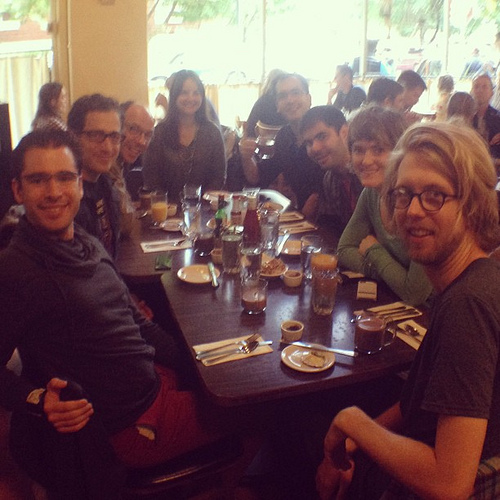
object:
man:
[320, 105, 499, 499]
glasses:
[382, 179, 460, 214]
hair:
[378, 115, 500, 254]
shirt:
[395, 256, 500, 454]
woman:
[324, 98, 436, 310]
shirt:
[333, 164, 442, 308]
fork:
[194, 326, 262, 361]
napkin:
[191, 325, 274, 372]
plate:
[280, 333, 337, 374]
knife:
[271, 335, 361, 358]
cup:
[275, 318, 305, 341]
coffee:
[286, 323, 296, 330]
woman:
[140, 66, 229, 187]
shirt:
[139, 111, 233, 187]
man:
[239, 64, 350, 217]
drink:
[253, 131, 278, 164]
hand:
[237, 138, 260, 161]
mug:
[234, 270, 273, 317]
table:
[160, 244, 441, 418]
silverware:
[199, 340, 262, 366]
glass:
[253, 198, 283, 255]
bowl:
[161, 219, 187, 233]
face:
[393, 170, 449, 264]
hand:
[317, 402, 353, 500]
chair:
[379, 447, 499, 492]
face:
[348, 134, 390, 190]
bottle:
[239, 196, 264, 246]